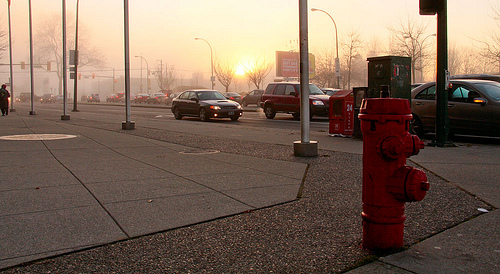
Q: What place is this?
A: It is a city.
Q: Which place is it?
A: It is a city.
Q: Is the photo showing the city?
A: Yes, it is showing the city.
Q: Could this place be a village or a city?
A: It is a city.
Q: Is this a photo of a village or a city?
A: It is showing a city.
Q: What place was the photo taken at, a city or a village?
A: It was taken at a city.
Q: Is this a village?
A: No, it is a city.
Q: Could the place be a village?
A: No, it is a city.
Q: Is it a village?
A: No, it is a city.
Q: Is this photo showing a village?
A: No, the picture is showing a city.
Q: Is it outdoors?
A: Yes, it is outdoors.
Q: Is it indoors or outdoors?
A: It is outdoors.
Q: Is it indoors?
A: No, it is outdoors.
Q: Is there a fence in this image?
A: No, there are no fences.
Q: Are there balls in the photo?
A: No, there are no balls.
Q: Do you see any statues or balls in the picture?
A: No, there are no balls or statues.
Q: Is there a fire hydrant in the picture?
A: Yes, there is a fire hydrant.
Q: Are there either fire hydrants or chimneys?
A: Yes, there is a fire hydrant.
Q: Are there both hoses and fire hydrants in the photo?
A: No, there is a fire hydrant but no hoses.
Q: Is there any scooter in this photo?
A: No, there are no scooters.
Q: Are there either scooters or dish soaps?
A: No, there are no scooters or dish soaps.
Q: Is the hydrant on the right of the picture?
A: Yes, the hydrant is on the right of the image.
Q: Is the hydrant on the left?
A: No, the hydrant is on the right of the image.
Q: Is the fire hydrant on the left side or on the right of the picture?
A: The fire hydrant is on the right of the image.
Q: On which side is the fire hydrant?
A: The fire hydrant is on the right of the image.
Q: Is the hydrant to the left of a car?
A: No, the hydrant is to the right of a car.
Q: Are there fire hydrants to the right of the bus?
A: Yes, there is a fire hydrant to the right of the bus.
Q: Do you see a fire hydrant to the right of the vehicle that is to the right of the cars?
A: Yes, there is a fire hydrant to the right of the bus.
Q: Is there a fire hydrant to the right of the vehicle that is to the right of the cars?
A: Yes, there is a fire hydrant to the right of the bus.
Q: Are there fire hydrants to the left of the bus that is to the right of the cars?
A: No, the fire hydrant is to the right of the bus.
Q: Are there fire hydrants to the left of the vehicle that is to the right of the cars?
A: No, the fire hydrant is to the right of the bus.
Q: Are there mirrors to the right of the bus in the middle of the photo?
A: No, there is a fire hydrant to the right of the bus.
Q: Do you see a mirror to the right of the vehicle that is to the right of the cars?
A: No, there is a fire hydrant to the right of the bus.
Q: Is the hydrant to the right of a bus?
A: Yes, the hydrant is to the right of a bus.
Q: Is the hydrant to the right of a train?
A: No, the hydrant is to the right of a bus.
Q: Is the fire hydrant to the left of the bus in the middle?
A: No, the fire hydrant is to the right of the bus.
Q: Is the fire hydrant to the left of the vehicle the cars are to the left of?
A: No, the fire hydrant is to the right of the bus.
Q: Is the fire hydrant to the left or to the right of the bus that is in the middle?
A: The fire hydrant is to the right of the bus.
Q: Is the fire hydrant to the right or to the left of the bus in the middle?
A: The fire hydrant is to the right of the bus.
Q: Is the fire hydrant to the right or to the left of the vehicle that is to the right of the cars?
A: The fire hydrant is to the right of the bus.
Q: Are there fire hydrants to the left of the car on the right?
A: Yes, there is a fire hydrant to the left of the car.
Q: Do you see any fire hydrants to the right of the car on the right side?
A: No, the fire hydrant is to the left of the car.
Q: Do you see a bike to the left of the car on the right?
A: No, there is a fire hydrant to the left of the car.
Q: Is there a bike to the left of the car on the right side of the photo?
A: No, there is a fire hydrant to the left of the car.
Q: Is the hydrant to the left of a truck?
A: No, the hydrant is to the left of a car.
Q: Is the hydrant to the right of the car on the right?
A: No, the hydrant is to the left of the car.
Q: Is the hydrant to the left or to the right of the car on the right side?
A: The hydrant is to the left of the car.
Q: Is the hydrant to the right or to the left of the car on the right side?
A: The hydrant is to the left of the car.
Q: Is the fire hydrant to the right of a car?
A: Yes, the fire hydrant is to the right of a car.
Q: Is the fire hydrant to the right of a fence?
A: No, the fire hydrant is to the right of a car.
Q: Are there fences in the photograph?
A: No, there are no fences.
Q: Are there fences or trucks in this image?
A: No, there are no fences or trucks.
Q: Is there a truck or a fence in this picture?
A: No, there are no fences or trucks.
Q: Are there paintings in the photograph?
A: No, there are no paintings.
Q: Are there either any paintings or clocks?
A: No, there are no paintings or clocks.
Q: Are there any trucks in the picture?
A: No, there are no trucks.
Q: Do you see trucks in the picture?
A: No, there are no trucks.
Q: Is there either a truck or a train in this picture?
A: No, there are no trucks or trains.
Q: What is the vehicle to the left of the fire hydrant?
A: The vehicle is a car.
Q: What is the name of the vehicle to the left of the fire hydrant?
A: The vehicle is a car.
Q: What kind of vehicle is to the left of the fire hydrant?
A: The vehicle is a car.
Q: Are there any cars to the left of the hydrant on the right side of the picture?
A: Yes, there is a car to the left of the hydrant.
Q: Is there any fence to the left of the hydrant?
A: No, there is a car to the left of the hydrant.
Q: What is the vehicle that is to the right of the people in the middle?
A: The vehicle is a car.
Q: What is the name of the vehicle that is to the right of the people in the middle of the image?
A: The vehicle is a car.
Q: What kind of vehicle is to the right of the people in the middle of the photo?
A: The vehicle is a car.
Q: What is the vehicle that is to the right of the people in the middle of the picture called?
A: The vehicle is a car.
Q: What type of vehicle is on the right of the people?
A: The vehicle is a car.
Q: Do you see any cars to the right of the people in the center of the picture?
A: Yes, there is a car to the right of the people.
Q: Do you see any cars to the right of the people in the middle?
A: Yes, there is a car to the right of the people.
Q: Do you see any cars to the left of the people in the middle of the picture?
A: No, the car is to the right of the people.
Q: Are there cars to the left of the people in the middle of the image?
A: No, the car is to the right of the people.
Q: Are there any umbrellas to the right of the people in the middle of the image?
A: No, there is a car to the right of the people.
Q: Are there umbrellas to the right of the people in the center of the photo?
A: No, there is a car to the right of the people.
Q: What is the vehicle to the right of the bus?
A: The vehicle is a car.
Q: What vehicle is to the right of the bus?
A: The vehicle is a car.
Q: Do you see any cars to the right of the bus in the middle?
A: Yes, there is a car to the right of the bus.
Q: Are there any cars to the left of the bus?
A: No, the car is to the right of the bus.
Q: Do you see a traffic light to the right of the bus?
A: No, there is a car to the right of the bus.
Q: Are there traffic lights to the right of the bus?
A: No, there is a car to the right of the bus.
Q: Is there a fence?
A: No, there are no fences.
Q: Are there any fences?
A: No, there are no fences.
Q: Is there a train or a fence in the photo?
A: No, there are no fences or trains.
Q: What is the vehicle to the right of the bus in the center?
A: The vehicle is a car.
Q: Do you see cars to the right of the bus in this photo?
A: Yes, there is a car to the right of the bus.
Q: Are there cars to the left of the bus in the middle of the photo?
A: No, the car is to the right of the bus.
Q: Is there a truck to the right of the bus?
A: No, there is a car to the right of the bus.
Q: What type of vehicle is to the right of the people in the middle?
A: The vehicle is a car.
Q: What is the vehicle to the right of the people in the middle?
A: The vehicle is a car.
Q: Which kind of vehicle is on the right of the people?
A: The vehicle is a car.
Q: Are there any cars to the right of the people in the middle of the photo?
A: Yes, there is a car to the right of the people.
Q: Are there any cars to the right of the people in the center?
A: Yes, there is a car to the right of the people.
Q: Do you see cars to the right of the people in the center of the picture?
A: Yes, there is a car to the right of the people.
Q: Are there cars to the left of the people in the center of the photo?
A: No, the car is to the right of the people.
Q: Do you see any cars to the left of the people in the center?
A: No, the car is to the right of the people.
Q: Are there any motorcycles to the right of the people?
A: No, there is a car to the right of the people.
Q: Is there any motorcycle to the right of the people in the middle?
A: No, there is a car to the right of the people.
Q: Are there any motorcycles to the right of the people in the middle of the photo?
A: No, there is a car to the right of the people.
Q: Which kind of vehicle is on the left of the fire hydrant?
A: The vehicle is a car.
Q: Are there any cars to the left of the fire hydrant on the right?
A: Yes, there is a car to the left of the hydrant.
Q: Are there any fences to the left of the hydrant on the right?
A: No, there is a car to the left of the fire hydrant.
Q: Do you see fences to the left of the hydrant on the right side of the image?
A: No, there is a car to the left of the fire hydrant.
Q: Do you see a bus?
A: Yes, there is a bus.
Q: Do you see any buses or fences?
A: Yes, there is a bus.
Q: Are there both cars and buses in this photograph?
A: Yes, there are both a bus and a car.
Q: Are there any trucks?
A: No, there are no trucks.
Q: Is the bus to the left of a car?
A: Yes, the bus is to the left of a car.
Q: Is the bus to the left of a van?
A: No, the bus is to the left of a car.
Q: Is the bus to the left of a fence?
A: No, the bus is to the left of the car.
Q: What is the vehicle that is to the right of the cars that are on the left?
A: The vehicle is a bus.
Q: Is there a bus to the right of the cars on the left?
A: Yes, there is a bus to the right of the cars.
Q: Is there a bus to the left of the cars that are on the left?
A: No, the bus is to the right of the cars.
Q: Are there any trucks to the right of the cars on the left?
A: No, there is a bus to the right of the cars.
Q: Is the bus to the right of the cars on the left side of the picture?
A: Yes, the bus is to the right of the cars.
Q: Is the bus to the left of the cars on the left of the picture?
A: No, the bus is to the right of the cars.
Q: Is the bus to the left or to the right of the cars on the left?
A: The bus is to the right of the cars.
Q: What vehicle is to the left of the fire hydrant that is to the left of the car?
A: The vehicle is a bus.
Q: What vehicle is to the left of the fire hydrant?
A: The vehicle is a bus.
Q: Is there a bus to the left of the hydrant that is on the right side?
A: Yes, there is a bus to the left of the fire hydrant.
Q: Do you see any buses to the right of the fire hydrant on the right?
A: No, the bus is to the left of the fire hydrant.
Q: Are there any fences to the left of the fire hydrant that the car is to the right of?
A: No, there is a bus to the left of the fire hydrant.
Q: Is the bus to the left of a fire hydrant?
A: Yes, the bus is to the left of a fire hydrant.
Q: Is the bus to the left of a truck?
A: No, the bus is to the left of a fire hydrant.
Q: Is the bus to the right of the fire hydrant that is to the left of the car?
A: No, the bus is to the left of the fire hydrant.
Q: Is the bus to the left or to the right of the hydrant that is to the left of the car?
A: The bus is to the left of the fire hydrant.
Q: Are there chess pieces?
A: No, there are no chess pieces.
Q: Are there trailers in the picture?
A: No, there are no trailers.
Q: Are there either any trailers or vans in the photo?
A: No, there are no trailers or vans.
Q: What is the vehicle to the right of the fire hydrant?
A: The vehicle is a car.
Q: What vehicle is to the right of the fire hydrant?
A: The vehicle is a car.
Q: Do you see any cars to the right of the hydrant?
A: Yes, there is a car to the right of the hydrant.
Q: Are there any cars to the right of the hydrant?
A: Yes, there is a car to the right of the hydrant.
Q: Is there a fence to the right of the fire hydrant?
A: No, there is a car to the right of the fire hydrant.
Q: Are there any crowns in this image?
A: No, there are no crowns.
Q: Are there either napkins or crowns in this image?
A: No, there are no crowns or napkins.